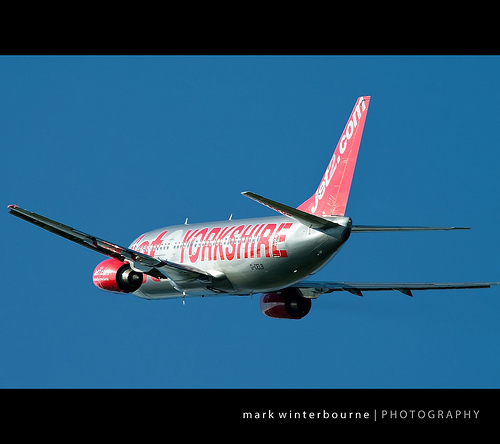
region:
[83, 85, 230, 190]
the sky is blue in colour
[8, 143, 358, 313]
it is silver in colour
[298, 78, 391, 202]
its tail is red in colour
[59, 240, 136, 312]
the engines are red in colour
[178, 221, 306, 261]
it has a red name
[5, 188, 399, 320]
it is flying on the skies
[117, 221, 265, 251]
it has many windows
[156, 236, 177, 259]
its door is closed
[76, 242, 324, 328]
it has a double engine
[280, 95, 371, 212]
the tail has a name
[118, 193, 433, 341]
the plane is driving in the atmosphere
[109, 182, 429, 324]
the plane is silver in color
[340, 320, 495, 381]
the sky is blue in color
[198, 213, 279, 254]
the words are written in red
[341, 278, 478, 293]
thje wings are black in color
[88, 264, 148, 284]
the piper is red in color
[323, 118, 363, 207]
the tail is red in color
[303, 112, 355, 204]
the words are written on a red tail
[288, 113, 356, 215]
the words are written in white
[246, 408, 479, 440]
words are written in white color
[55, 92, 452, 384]
Sky is blue color.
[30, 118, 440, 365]
Plane is flying in air.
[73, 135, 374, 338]
Plane is grey and red color.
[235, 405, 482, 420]
Letters are white color.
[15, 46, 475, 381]
Day time picture.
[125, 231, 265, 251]
Windows are fixed to the sides of the plane.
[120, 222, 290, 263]
Letters are red color.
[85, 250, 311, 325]
Two engine is seen in both wings.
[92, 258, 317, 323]
Engine is red color.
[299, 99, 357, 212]
Letters on wings are white color.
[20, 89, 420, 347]
the plane is in the air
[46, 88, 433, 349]
the plane is flying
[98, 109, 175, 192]
the sky is blue in colour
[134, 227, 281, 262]
it is written in red colour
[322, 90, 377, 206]
the tail is red in colour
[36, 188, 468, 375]
it has four wings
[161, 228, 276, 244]
it has many windows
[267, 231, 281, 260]
the door is closed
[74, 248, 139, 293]
the engine are red in colour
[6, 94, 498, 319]
the airplane in the sky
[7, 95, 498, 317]
the airplane in mid air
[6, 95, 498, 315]
the red areas on the airplane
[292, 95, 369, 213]
the tail on the plane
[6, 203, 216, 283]
the wing on the plane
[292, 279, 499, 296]
the wine on the plane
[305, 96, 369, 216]
the words on the tail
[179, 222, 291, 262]
the word "YORKSHIRE" on the plane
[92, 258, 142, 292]
the engine on the plane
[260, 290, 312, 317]
the engine on the plane